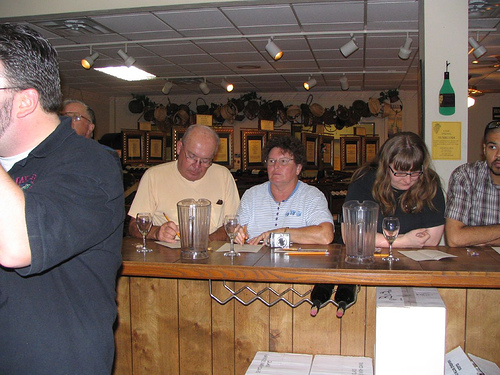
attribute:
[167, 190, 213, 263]
pitcher — empty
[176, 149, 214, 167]
eye glasses — a pair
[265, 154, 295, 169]
eye glasses — a pair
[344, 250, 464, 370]
wrap — plastic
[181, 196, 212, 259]
jug — glass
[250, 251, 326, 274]
tabletop — wooden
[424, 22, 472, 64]
pillar — white 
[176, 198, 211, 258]
pitcher — glass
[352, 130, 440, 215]
hair — long, brown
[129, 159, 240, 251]
shirt — yellow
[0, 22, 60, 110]
hair — brown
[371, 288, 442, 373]
box — white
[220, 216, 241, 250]
glass — empty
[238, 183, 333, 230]
shirt — blue, white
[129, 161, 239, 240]
shirt — yellow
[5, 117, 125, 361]
shirt — blue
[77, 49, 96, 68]
light — white, ceiling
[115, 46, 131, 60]
light — white, ceiling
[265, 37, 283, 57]
light — white, ceiling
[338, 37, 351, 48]
light — white, ceiling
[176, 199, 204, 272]
pitcher — empty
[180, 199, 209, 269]
pitcher — empty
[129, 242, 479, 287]
counter — empty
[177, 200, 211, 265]
pitcher — empty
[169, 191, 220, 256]
pitcher — empty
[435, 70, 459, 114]
cozy — green